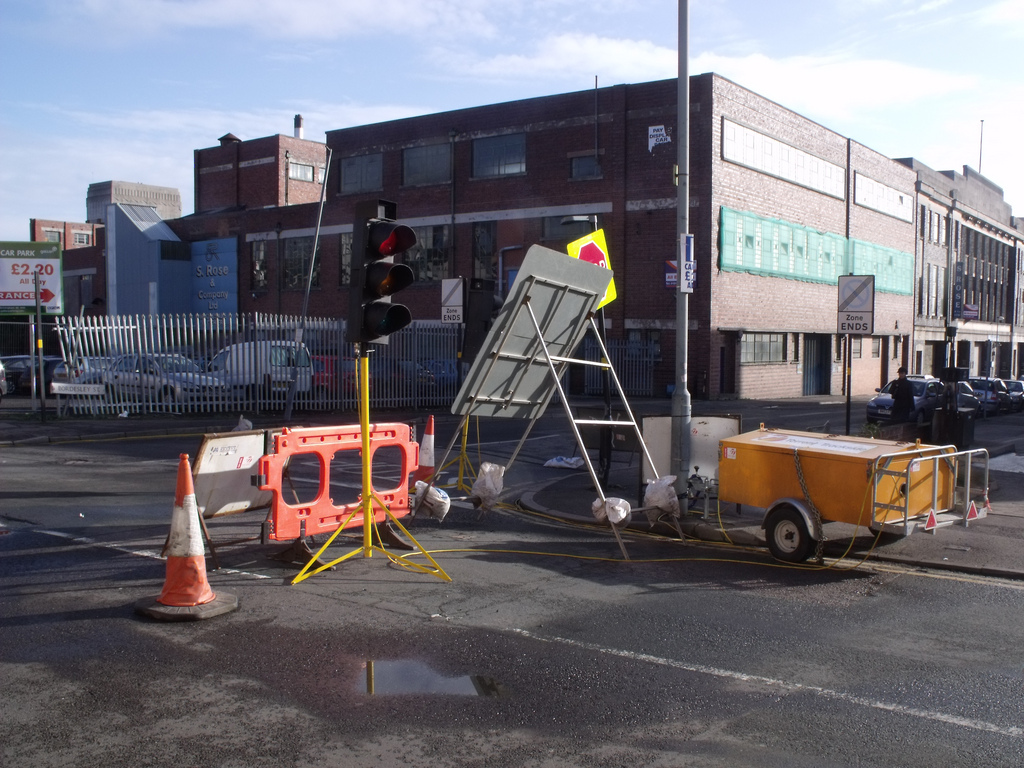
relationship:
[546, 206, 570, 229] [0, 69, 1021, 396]
window on building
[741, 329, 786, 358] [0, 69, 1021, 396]
window on building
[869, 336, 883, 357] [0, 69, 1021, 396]
window on building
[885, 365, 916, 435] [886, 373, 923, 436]
person in dress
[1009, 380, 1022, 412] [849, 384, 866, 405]
car parked on curb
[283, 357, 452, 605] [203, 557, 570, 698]
yellow pole on ground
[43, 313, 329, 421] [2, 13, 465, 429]
fence in background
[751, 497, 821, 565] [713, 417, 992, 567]
wheel on cart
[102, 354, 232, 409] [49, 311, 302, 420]
car parked behind fence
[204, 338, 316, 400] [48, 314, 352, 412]
white van behind fence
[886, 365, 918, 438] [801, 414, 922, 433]
person standing on street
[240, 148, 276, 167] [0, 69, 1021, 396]
window on building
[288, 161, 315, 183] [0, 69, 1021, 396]
window on a building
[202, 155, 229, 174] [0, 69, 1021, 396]
window on building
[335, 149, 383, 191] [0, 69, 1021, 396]
window on building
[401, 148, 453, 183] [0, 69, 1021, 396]
window on building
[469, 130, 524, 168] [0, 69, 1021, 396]
window on building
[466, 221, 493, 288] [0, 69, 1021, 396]
window on building